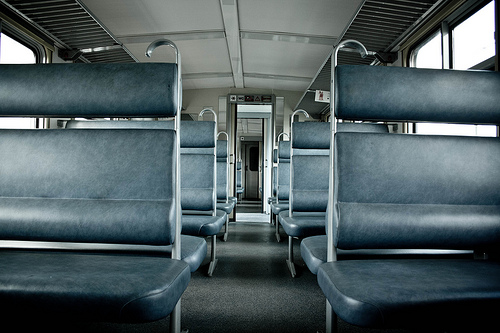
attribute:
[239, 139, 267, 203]
door — white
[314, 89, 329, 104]
sign — white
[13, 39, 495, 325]
seats — several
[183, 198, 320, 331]
walk-way — grey, marbled, walk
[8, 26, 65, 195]
window — dark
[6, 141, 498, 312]
area — seating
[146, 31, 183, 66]
hook — steel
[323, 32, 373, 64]
hook — steel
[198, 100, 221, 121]
hook — steel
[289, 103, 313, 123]
hook — steel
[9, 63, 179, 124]
rest — head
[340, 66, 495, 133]
rest — head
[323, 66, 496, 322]
seat — train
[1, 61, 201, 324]
seat — train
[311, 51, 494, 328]
seat — bluish gray